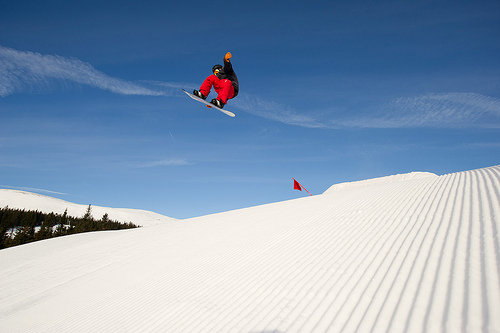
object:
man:
[185, 52, 239, 108]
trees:
[0, 207, 144, 249]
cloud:
[0, 42, 497, 130]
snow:
[0, 166, 500, 333]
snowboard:
[181, 88, 236, 118]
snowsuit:
[189, 57, 240, 104]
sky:
[0, 0, 500, 197]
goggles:
[213, 69, 220, 76]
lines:
[436, 178, 491, 325]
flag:
[294, 179, 303, 192]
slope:
[0, 164, 499, 333]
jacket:
[212, 56, 239, 99]